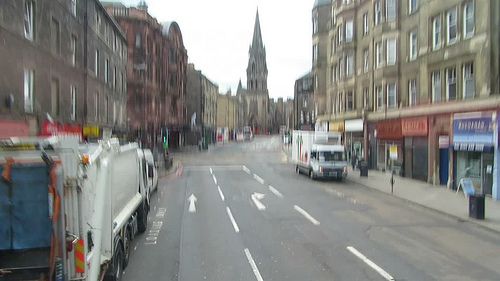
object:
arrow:
[188, 193, 198, 212]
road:
[120, 134, 499, 280]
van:
[292, 127, 346, 182]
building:
[236, 7, 268, 133]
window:
[22, 64, 37, 117]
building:
[0, 2, 130, 140]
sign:
[344, 120, 364, 133]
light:
[163, 137, 166, 143]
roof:
[158, 21, 176, 37]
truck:
[1, 135, 150, 278]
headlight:
[319, 166, 323, 172]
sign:
[375, 118, 403, 139]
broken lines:
[205, 165, 394, 281]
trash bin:
[468, 194, 486, 220]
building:
[101, 2, 188, 151]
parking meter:
[390, 170, 393, 194]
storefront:
[453, 111, 497, 198]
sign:
[389, 144, 398, 160]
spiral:
[72, 237, 86, 274]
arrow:
[251, 192, 267, 210]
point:
[247, 7, 267, 70]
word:
[146, 204, 166, 245]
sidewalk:
[347, 158, 497, 232]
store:
[376, 120, 404, 174]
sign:
[451, 113, 494, 151]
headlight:
[344, 166, 347, 172]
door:
[439, 149, 448, 185]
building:
[397, 0, 499, 199]